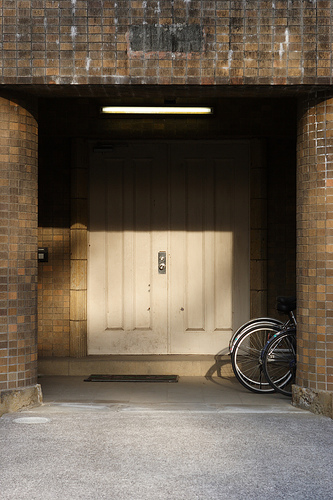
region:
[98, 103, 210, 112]
a bright outside light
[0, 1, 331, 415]
front of brick building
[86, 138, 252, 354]
a double white door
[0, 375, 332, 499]
gray and white entrance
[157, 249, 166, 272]
silver plate door knob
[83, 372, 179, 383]
a black door mat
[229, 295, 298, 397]
three bicycles against wall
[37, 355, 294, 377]
a gray concrete platform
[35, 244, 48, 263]
a black and white sensor device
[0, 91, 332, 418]
two round brick supports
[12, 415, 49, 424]
light colored metallic drain cover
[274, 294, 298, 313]
two or three black bicycle wheels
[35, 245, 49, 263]
either a black mailbox or intercom system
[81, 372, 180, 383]
black rubber door mat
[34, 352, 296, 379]
long cement step that runs along the wall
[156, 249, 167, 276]
silver door plate with knob and lock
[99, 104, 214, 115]
three foot halogen light bulb over the door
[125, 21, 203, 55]
black square where address numbers used to be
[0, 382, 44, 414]
cement base to the brick wall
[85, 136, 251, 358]
one set of white double doors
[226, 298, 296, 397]
the back wheels of the bikes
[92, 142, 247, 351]
the front doors of the house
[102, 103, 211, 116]
the bright light in front of the house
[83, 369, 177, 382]
the door mat sitting on the ground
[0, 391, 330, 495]
the sidewalk leading to the house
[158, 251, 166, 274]
the knobs on the door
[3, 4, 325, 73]
the bricks placed on the wall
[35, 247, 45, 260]
a bell to ring by the door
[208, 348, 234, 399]
the shadows of the tires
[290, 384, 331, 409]
the bottom of the column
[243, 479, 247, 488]
part of a path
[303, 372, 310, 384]
part of a building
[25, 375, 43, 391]
part of a pillar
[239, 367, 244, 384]
edge of a wheel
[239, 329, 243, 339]
part of a wheel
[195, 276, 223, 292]
Small section of the beige door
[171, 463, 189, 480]
Small patch of the gray ground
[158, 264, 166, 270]
Silver doorknob on the door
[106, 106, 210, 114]
Bright light in front of the door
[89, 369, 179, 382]
Black rug in front of the door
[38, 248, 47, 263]
Small section of the mailbox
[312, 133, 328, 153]
Brown brick section of the pillar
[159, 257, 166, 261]
Silver door lock on door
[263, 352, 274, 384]
Small part of the black wheel of the first bike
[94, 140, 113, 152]
Silver object on top of the door